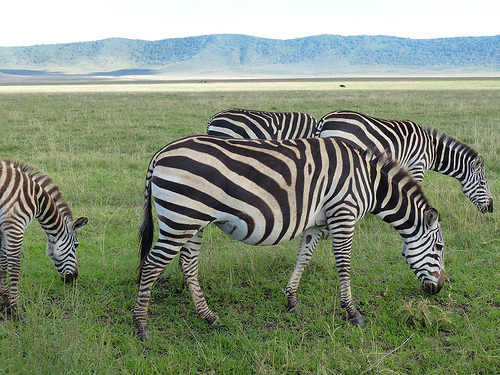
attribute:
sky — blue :
[152, 23, 464, 39]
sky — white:
[169, 1, 440, 22]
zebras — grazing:
[1, 159, 88, 324]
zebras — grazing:
[208, 110, 318, 137]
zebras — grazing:
[315, 109, 492, 213]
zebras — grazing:
[133, 135, 446, 344]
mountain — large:
[4, 22, 498, 87]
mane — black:
[422, 123, 475, 163]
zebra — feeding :
[197, 107, 317, 140]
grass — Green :
[308, 316, 491, 373]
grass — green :
[28, 75, 488, 367]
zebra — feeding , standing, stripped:
[129, 135, 446, 339]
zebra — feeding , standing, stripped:
[0, 153, 87, 320]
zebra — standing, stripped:
[208, 108, 318, 139]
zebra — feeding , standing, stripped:
[314, 107, 495, 211]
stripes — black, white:
[202, 153, 320, 240]